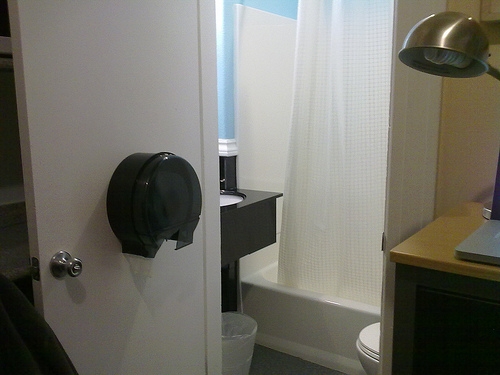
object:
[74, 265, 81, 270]
lock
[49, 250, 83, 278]
knob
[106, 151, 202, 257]
holder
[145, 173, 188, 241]
toilet paper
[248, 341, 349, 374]
floor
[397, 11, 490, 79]
lamp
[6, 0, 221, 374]
door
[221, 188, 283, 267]
counter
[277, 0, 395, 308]
curtain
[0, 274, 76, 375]
clothing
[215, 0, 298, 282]
wall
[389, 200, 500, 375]
shelf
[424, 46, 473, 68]
bulb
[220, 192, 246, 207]
sink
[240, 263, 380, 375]
bathtub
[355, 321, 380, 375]
lid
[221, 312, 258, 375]
bag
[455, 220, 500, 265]
base